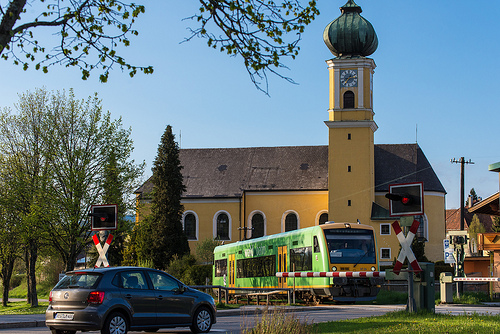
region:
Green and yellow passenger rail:
[206, 215, 381, 305]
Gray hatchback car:
[40, 265, 215, 330]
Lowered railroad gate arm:
[270, 180, 420, 310]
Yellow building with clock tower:
[130, 0, 440, 290]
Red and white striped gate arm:
[270, 220, 415, 280]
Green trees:
[0, 80, 130, 310]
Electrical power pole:
[445, 150, 475, 230]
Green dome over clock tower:
[320, 0, 375, 60]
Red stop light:
[385, 180, 425, 215]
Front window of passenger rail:
[320, 220, 380, 273]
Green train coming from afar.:
[212, 222, 374, 299]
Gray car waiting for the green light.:
[45, 267, 215, 332]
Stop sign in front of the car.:
[389, 218, 426, 275]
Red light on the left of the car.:
[387, 183, 422, 212]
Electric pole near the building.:
[448, 152, 473, 297]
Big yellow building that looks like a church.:
[133, 2, 448, 299]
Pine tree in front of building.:
[135, 122, 189, 267]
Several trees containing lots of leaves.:
[0, 88, 147, 301]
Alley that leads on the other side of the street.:
[0, 310, 408, 329]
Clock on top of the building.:
[337, 67, 359, 89]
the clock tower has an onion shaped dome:
[320, 0, 377, 220]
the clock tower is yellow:
[322, 55, 375, 216]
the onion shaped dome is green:
[320, 1, 380, 57]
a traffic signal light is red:
[380, 180, 427, 221]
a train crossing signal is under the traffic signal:
[386, 181, 426, 307]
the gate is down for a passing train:
[270, 258, 415, 303]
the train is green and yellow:
[205, 216, 381, 301]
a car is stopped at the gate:
[36, 255, 411, 326]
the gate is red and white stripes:
[275, 264, 413, 289]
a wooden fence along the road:
[181, 278, 301, 314]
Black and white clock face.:
[326, 64, 366, 93]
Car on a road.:
[34, 254, 231, 331]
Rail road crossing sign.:
[80, 238, 122, 273]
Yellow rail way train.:
[212, 209, 381, 306]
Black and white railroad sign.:
[370, 205, 435, 298]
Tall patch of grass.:
[236, 299, 318, 332]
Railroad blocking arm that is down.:
[412, 266, 496, 311]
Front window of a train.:
[307, 218, 382, 273]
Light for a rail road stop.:
[70, 198, 122, 238]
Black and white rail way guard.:
[242, 264, 387, 288]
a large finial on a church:
[303, 0, 383, 55]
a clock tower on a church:
[329, 56, 386, 118]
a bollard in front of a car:
[281, 260, 397, 285]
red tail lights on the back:
[42, 291, 118, 303]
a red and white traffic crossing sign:
[389, 212, 426, 287]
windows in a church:
[194, 201, 302, 235]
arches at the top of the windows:
[211, 206, 326, 221]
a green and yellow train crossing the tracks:
[209, 239, 345, 287]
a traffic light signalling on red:
[386, 187, 451, 211]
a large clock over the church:
[334, 66, 364, 86]